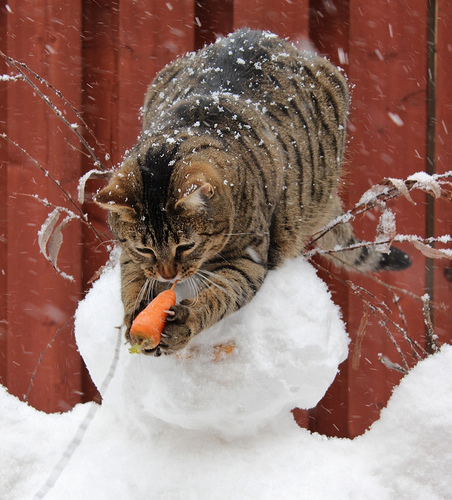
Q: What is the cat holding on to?
A: A carrot.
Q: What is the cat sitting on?
A: A snowman.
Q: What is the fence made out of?
A: Redwood.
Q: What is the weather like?
A: Cold and snowy.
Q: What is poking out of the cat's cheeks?
A: Whiskers.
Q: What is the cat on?
A: The head of a snowman.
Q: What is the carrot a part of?
A: The snowman.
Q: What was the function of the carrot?
A: The snowman's nose.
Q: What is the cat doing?
A: Eating the carrot.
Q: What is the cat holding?
A: A carrot.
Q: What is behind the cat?
A: Red fence.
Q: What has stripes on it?
A: The cat.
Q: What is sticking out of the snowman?
A: Small branches.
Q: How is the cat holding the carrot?
A: With its two front paws.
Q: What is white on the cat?
A: Snowflakes.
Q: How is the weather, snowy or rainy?
A: Snowy.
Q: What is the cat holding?
A: A carrot.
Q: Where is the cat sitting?
A: A snowman's head.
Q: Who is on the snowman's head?
A: A cat.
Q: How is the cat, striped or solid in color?
A: Striped.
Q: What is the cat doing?
A: Jumping.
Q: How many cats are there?
A: 1.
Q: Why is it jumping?
A: Reaching for carrot.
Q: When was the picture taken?
A: During the day.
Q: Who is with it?
A: No one.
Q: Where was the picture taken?
A: On a snowman.